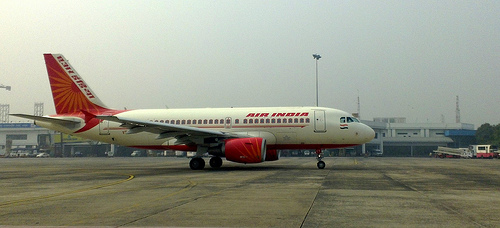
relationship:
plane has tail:
[10, 52, 377, 170] [45, 54, 110, 114]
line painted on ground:
[1, 170, 135, 201] [5, 158, 500, 227]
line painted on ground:
[1, 170, 198, 226] [5, 158, 500, 227]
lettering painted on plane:
[245, 112, 310, 118] [10, 52, 377, 170]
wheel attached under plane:
[316, 161, 326, 167] [10, 52, 377, 170]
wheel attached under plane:
[188, 156, 205, 171] [10, 52, 377, 170]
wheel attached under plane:
[209, 156, 223, 169] [10, 52, 377, 170]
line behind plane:
[1, 170, 135, 201] [10, 52, 377, 170]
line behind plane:
[1, 170, 198, 226] [10, 52, 377, 170]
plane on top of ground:
[10, 52, 377, 170] [5, 158, 500, 227]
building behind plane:
[0, 116, 475, 158] [10, 52, 377, 170]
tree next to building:
[476, 124, 491, 143] [0, 116, 475, 158]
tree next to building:
[491, 124, 499, 141] [0, 116, 475, 158]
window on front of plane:
[342, 117, 346, 125] [10, 52, 377, 170]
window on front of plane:
[348, 117, 352, 123] [10, 52, 377, 170]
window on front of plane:
[349, 116, 360, 122] [10, 52, 377, 170]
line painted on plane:
[102, 123, 311, 133] [10, 52, 377, 170]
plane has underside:
[10, 52, 377, 170] [122, 141, 362, 154]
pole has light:
[314, 52, 320, 105] [314, 52, 322, 59]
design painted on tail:
[48, 65, 98, 113] [45, 54, 110, 114]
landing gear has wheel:
[311, 147, 326, 171] [316, 161, 326, 167]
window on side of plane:
[306, 117, 311, 125] [10, 52, 377, 170]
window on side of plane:
[294, 116, 300, 125] [10, 52, 377, 170]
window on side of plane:
[282, 116, 288, 124] [10, 52, 377, 170]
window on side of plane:
[272, 117, 276, 123] [10, 52, 377, 170]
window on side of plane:
[249, 115, 254, 124] [10, 52, 377, 170]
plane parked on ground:
[10, 52, 377, 170] [5, 158, 500, 227]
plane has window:
[10, 52, 377, 170] [249, 115, 254, 124]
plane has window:
[10, 52, 377, 170] [272, 117, 276, 123]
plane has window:
[10, 52, 377, 170] [282, 116, 288, 124]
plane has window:
[10, 52, 377, 170] [294, 116, 300, 125]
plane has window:
[10, 52, 377, 170] [306, 117, 311, 125]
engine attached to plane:
[225, 137, 268, 163] [10, 52, 377, 170]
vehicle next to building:
[473, 144, 491, 156] [0, 116, 475, 158]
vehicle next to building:
[431, 145, 473, 159] [0, 116, 475, 158]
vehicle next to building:
[35, 153, 51, 157] [0, 116, 475, 158]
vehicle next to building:
[24, 148, 32, 156] [0, 116, 475, 158]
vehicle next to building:
[11, 148, 19, 158] [0, 116, 475, 158]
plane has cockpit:
[10, 52, 377, 170] [341, 114, 365, 132]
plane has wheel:
[10, 52, 377, 170] [316, 161, 326, 167]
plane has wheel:
[10, 52, 377, 170] [188, 156, 205, 171]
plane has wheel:
[10, 52, 377, 170] [209, 156, 223, 169]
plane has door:
[10, 52, 377, 170] [314, 112, 327, 132]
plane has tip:
[10, 52, 377, 170] [357, 121, 377, 146]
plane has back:
[10, 52, 377, 170] [37, 108, 113, 151]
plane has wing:
[10, 52, 377, 170] [89, 114, 239, 151]